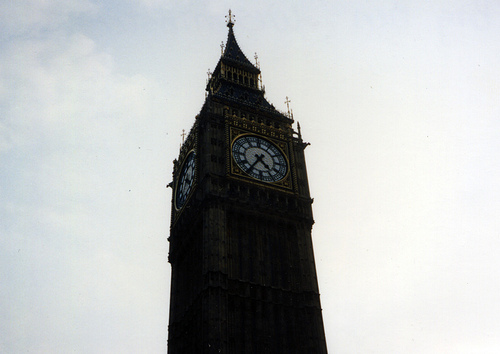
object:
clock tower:
[165, 7, 328, 354]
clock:
[175, 149, 198, 211]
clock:
[232, 135, 288, 183]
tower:
[165, 11, 327, 354]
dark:
[223, 227, 291, 331]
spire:
[208, 5, 266, 87]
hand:
[246, 154, 271, 174]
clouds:
[48, 44, 113, 146]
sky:
[3, 3, 492, 352]